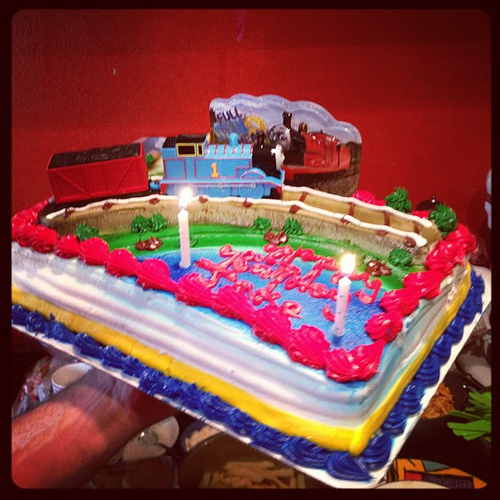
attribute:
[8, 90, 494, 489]
cake — child's, blue, yellow, white, multicolored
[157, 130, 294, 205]
train — thomas, decoration, toy, blue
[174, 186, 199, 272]
candle — lit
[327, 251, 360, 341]
candle — lit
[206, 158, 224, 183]
number — one, yellow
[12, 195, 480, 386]
icing — pink, border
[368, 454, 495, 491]
plate — paper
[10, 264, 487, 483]
icing — blue, yellow, purple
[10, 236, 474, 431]
icing — white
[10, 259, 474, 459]
icing — yellow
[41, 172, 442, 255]
track — icing, frosting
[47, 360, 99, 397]
cup — white, blue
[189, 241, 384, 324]
writing — icing, pink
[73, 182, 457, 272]
trees — frosting, mini, green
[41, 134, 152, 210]
car — red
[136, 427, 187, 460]
spoon — laying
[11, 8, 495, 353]
wall — red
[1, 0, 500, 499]
photo — indoors, colorful